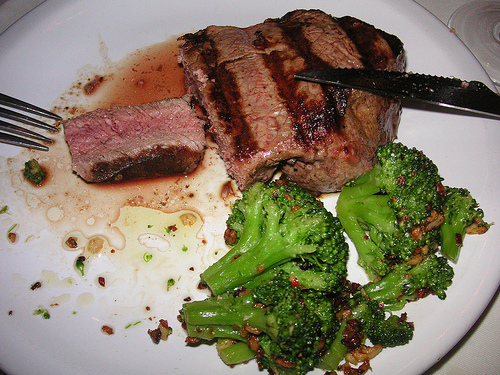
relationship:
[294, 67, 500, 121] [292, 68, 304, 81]
blade has sharp tip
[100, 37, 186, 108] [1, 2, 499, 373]
soup remnants are on top of plate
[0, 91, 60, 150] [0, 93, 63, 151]
fork has fork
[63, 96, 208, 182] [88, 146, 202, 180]
meat has dark portion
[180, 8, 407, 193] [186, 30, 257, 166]
meat has dark portion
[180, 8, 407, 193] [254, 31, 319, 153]
meat has dark portion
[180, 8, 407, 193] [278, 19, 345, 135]
meat has dark portion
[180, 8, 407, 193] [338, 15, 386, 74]
meat has dark portion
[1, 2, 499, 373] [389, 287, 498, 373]
plate has rim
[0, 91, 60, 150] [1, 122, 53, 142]
fork has tine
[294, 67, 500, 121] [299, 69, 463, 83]
blade has blade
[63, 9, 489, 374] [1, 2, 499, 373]
meal on top of plate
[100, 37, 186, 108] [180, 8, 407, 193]
soup remnants are outside of meat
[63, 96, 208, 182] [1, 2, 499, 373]
meat on top of plate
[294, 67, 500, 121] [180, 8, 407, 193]
blade on top of meat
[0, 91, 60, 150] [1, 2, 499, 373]
fork on top of plate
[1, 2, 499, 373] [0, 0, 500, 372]
plate on top of plate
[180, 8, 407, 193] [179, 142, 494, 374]
meat on top of broccoli bunch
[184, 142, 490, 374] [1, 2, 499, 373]
broccoli bunch on top of plate